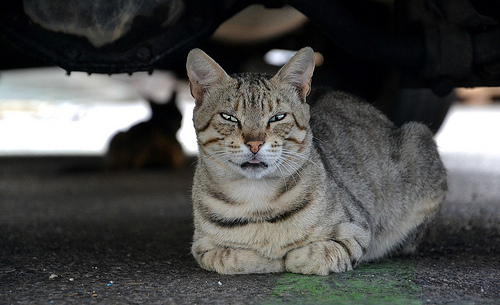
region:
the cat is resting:
[165, 45, 468, 286]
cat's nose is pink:
[235, 118, 270, 157]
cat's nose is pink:
[244, 130, 265, 156]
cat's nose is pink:
[242, 128, 282, 160]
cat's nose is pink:
[239, 125, 279, 182]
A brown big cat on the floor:
[201, 87, 443, 255]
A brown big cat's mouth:
[240, 159, 262, 180]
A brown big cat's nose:
[244, 134, 263, 155]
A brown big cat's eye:
[270, 111, 287, 131]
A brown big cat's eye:
[220, 111, 246, 130]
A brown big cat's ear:
[272, 49, 319, 95]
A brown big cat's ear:
[176, 49, 218, 93]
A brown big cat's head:
[175, 50, 320, 200]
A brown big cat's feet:
[197, 220, 343, 272]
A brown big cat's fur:
[332, 84, 441, 217]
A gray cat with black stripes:
[185, 45, 447, 274]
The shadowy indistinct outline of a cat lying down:
[101, 90, 189, 166]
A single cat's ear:
[177, 42, 234, 96]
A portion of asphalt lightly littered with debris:
[15, 241, 169, 296]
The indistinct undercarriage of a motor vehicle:
[12, 3, 159, 81]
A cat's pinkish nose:
[243, 138, 265, 155]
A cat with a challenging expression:
[182, 49, 326, 183]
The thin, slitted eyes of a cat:
[215, 110, 292, 131]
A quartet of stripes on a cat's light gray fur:
[201, 188, 316, 226]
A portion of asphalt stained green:
[294, 278, 434, 304]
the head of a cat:
[190, 0, 435, 155]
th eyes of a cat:
[210, 95, 320, 135]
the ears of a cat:
[148, 41, 331, 131]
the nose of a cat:
[213, 129, 291, 175]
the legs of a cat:
[215, 218, 366, 283]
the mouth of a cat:
[201, 129, 356, 209]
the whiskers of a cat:
[194, 123, 341, 198]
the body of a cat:
[231, 86, 446, 273]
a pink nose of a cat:
[231, 122, 285, 167]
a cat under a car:
[160, 88, 407, 300]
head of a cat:
[185, 41, 322, 182]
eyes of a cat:
[215, 105, 287, 128]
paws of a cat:
[206, 214, 367, 291]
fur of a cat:
[345, 150, 392, 210]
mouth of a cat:
[219, 123, 291, 175]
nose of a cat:
[245, 133, 264, 151]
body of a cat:
[304, 90, 461, 234]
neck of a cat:
[211, 172, 318, 209]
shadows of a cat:
[451, 223, 497, 273]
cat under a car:
[102, 88, 187, 168]